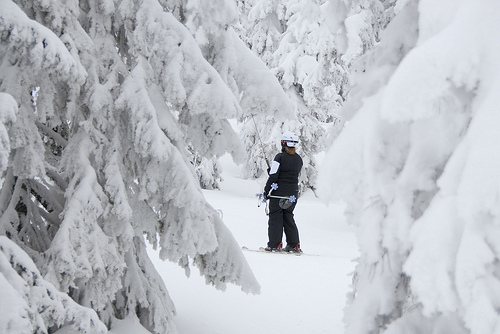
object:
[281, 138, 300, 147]
goggles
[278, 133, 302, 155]
head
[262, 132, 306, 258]
person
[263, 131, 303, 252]
guy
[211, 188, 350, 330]
snow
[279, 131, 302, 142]
hat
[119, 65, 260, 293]
branch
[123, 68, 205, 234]
snow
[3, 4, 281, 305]
trees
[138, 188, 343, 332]
ground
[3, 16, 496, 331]
forest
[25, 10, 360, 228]
scenery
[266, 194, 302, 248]
pants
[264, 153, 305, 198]
jacket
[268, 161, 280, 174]
patches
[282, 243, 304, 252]
boots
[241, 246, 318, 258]
skiis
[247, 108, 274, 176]
pole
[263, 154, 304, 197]
coat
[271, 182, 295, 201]
baskets